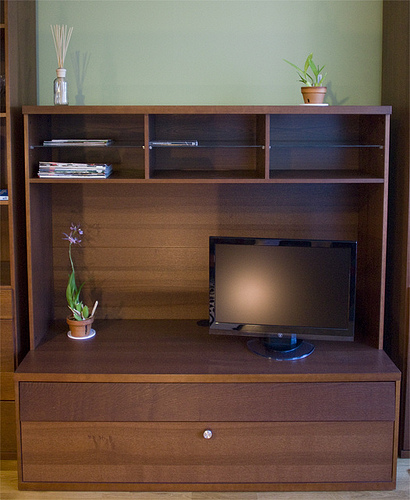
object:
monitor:
[208, 235, 358, 361]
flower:
[62, 222, 84, 247]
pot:
[66, 314, 94, 338]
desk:
[117, 321, 189, 372]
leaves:
[283, 58, 305, 74]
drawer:
[20, 382, 395, 484]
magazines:
[38, 161, 113, 179]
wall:
[119, 0, 249, 91]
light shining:
[229, 270, 274, 320]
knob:
[203, 429, 213, 440]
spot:
[85, 325, 88, 334]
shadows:
[72, 50, 91, 106]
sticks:
[50, 25, 60, 68]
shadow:
[86, 271, 126, 332]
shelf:
[30, 178, 384, 184]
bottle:
[54, 68, 68, 105]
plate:
[67, 329, 96, 340]